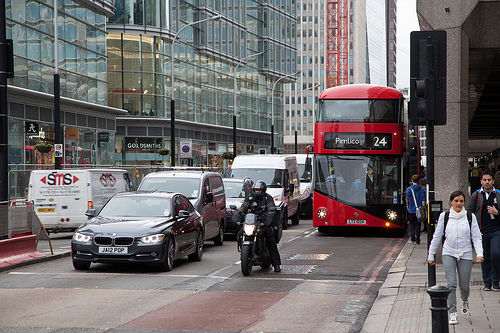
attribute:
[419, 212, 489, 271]
jacket —  white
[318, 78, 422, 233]
bus — with destination, with  number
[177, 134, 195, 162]
signs — for direction,  a Bunch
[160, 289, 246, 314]
signs —  a Bunch, for direction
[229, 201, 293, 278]
motorcycle —  black,  rider's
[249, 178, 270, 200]
helmet — for motorcycle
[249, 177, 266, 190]
helmet —  black, for crash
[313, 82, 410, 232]
bus — red, double decker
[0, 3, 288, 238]
building —  tall 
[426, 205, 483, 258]
shirt —  black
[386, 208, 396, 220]
headlights —  on, of  bus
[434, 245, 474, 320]
pants — grey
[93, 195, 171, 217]
windshield —  car's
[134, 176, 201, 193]
windshield —  car's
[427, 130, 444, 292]
pole —  black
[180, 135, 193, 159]
direction sign — a Bunch 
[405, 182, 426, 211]
hoodie —  blue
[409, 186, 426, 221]
bag —  cross shoulder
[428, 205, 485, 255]
jacket — white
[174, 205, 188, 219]
mirror —  for side view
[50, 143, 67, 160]
signs — for direction, a Bunch 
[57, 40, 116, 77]
windows —  many,  glass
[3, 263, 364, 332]
street —  busy